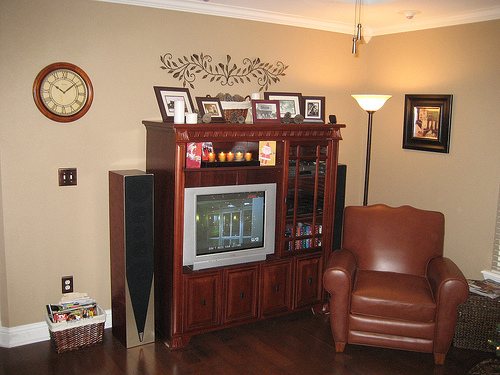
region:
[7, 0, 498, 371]
This is a living room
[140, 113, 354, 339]
This is an entertainment center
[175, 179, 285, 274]
This is a TV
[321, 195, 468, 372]
This is a leather chair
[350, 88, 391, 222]
This is a lamp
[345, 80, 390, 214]
The lamp is on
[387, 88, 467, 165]
This is a framed picture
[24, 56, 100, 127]
This is a clock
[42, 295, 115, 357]
This is a basket of magazines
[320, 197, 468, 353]
a brown leather chair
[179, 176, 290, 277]
a silver tv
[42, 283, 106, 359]
a basket with magazines in it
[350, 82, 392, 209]
a tall floor lamp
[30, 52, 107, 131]
a clock hanging on the wall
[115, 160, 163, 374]
a tall speaker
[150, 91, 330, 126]
several framed pictures on top of a entertainment center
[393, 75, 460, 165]
a picture hanging on the a wall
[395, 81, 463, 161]
a framed picture hanging on the wall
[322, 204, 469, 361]
A brown leather easy chair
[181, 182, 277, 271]
A gray flat screen TV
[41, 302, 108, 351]
A wicker basket on the floor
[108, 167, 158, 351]
A tall wood stereo speaker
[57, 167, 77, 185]
A wood light switch on the wall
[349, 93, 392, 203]
A tall black lamp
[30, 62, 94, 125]
A round clock on the wall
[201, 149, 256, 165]
A row of candles on the shelf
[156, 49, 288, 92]
Decorative art on the wall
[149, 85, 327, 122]
Framed pictures on the cabinet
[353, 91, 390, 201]
Floor lamp in the corner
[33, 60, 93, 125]
Clock on the wall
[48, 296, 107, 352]
Wicker basket with magazines on the floor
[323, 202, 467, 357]
Leather chair in the corner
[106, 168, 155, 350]
Large speaker to left of cabinet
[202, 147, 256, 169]
Lit candles on the shelf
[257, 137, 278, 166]
Santa Claus card on the shelf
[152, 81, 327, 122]
Pictures on top of the cabinet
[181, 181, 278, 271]
Television with silver frame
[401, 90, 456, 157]
Framed picture on the wall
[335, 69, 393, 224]
lit torch like lamp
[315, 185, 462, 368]
leather chair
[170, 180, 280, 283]
built in television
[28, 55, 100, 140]
wall clock indicating ten ten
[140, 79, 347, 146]
row of picture frames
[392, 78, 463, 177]
framed picture on wall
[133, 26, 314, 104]
black wall scroll on brown wall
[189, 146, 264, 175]
row of lit candles in recess of a hutch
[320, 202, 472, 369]
brown leather armchair with wood legs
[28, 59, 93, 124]
brown wood frame with beige face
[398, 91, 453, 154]
picture inside of black wood frame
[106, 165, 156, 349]
black and wood speaker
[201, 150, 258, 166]
row of lit candles on black tray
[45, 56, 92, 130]
clock on the wall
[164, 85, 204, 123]
picture on the stand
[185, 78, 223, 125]
picture on the stand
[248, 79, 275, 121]
picture on the stand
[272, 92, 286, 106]
picture on the stand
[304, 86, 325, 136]
picture on the stand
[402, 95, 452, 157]
a miror on the wall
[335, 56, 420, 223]
a lamp turned on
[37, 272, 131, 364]
a basket on the floor